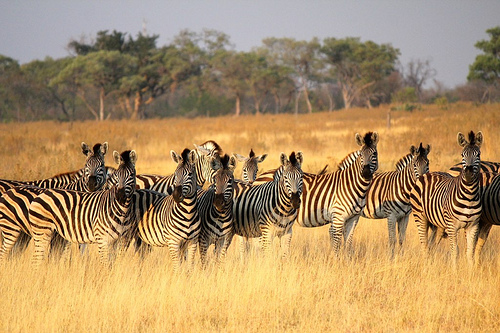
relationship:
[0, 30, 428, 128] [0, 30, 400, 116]
leaves on tree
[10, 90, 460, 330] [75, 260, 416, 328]
field of grass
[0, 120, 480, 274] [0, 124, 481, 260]
herd of zebras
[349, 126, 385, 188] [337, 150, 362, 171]
head with hair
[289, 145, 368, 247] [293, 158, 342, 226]
stripes on torso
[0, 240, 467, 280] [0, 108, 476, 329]
feet obstructed by grass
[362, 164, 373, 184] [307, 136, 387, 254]
nose of zebra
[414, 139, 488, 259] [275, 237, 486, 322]
zebra standing in field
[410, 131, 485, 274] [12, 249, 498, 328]
zebra standing in field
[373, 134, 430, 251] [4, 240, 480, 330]
zebra standing in field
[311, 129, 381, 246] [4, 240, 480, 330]
zebra standing in field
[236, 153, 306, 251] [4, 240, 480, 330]
zebra standing in field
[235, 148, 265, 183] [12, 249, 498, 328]
zebra standing in field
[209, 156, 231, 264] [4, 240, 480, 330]
zebra standing in field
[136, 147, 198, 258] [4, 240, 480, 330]
zebra standing in field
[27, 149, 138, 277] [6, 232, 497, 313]
zebra standing in field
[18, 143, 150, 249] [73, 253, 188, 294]
zebra in field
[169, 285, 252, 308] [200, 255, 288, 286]
grass on ground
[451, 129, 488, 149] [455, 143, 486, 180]
ears on head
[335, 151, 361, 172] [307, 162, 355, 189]
hair on back